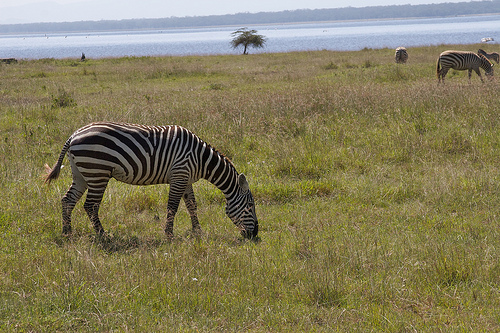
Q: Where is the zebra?
A: In the grass.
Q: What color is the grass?
A: Green.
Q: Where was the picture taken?
A: In a field.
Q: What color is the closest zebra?
A: Black and white.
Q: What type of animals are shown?
A: Zebras.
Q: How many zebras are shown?
A: 4.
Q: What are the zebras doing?
A: Eating.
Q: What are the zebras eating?
A: Grass.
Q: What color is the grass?
A: Brown and green.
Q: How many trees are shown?
A: 1.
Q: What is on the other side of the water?
A: Hills.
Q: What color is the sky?
A: Light blue.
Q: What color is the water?
A: Blue.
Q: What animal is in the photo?
A: Zebra.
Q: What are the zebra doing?
A: Grazing.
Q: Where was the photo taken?
A: In the open plains.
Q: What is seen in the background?
A: Water.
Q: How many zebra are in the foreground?
A: 1.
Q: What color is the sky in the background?
A: Blue.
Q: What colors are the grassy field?
A: Green and brown.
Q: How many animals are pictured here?
A: Four.